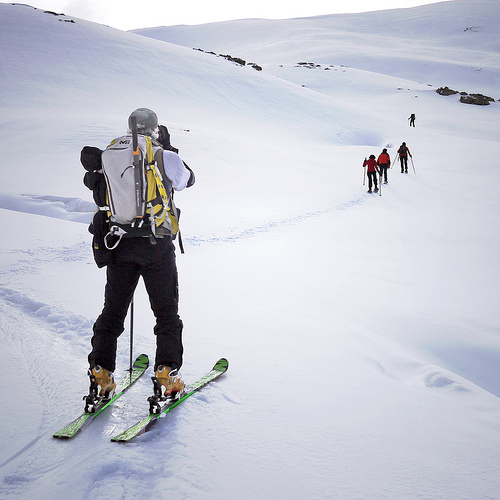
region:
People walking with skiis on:
[15, 70, 437, 449]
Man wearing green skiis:
[46, 98, 233, 475]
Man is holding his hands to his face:
[113, 89, 187, 187]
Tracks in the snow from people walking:
[1, 103, 365, 363]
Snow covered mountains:
[4, 0, 484, 473]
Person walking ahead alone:
[398, 88, 432, 132]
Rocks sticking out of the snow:
[435, 79, 496, 112]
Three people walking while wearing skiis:
[353, 137, 425, 200]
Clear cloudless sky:
[6, 1, 481, 29]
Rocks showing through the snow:
[190, 30, 275, 72]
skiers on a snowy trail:
[355, 110, 425, 197]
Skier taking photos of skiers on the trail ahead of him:
[51, 104, 233, 445]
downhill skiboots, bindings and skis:
[51, 348, 241, 450]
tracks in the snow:
[0, 285, 91, 363]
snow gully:
[411, 332, 498, 394]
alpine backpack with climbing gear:
[76, 132, 180, 260]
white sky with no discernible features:
[0, 0, 497, 33]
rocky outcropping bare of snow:
[433, 82, 498, 112]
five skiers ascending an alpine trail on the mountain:
[25, 97, 424, 454]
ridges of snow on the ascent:
[1, 0, 498, 104]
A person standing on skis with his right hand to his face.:
[84, 106, 196, 411]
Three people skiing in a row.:
[362, 139, 414, 192]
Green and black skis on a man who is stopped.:
[52, 357, 229, 442]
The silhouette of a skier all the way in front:
[407, 112, 417, 125]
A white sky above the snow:
[18, 0, 495, 31]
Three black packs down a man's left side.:
[81, 144, 118, 270]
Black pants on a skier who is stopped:
[88, 231, 185, 372]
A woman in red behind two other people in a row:
[363, 154, 380, 194]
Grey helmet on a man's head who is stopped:
[128, 105, 158, 140]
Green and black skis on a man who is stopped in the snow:
[54, 355, 229, 444]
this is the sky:
[132, 10, 159, 20]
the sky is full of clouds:
[124, 4, 166, 28]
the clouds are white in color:
[107, 4, 149, 19]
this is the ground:
[302, 348, 397, 438]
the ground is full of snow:
[281, 365, 348, 440]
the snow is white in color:
[268, 361, 355, 467]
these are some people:
[71, 95, 458, 410]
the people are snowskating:
[51, 88, 422, 440]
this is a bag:
[101, 135, 161, 225]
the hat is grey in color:
[131, 108, 161, 125]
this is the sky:
[106, 0, 143, 17]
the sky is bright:
[111, 3, 141, 23]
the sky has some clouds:
[111, 8, 145, 24]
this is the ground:
[256, 328, 447, 468]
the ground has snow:
[263, 346, 347, 427]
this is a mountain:
[23, 3, 84, 93]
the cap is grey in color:
[134, 110, 153, 130]